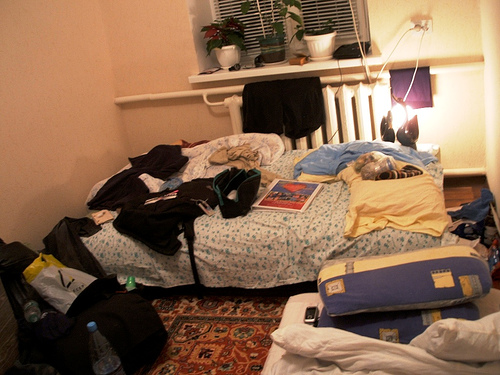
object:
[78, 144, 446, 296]
bed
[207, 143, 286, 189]
thing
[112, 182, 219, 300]
thing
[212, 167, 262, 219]
thing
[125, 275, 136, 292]
bottle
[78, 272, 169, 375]
bag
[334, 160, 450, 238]
pillow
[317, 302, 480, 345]
pillow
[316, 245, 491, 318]
pillow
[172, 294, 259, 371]
rug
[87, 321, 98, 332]
cap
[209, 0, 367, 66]
window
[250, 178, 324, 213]
book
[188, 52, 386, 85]
window sill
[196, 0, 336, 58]
plants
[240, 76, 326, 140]
black shorts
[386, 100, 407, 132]
light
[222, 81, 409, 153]
headboard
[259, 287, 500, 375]
chair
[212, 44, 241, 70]
pot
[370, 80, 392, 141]
lamp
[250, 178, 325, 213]
magazine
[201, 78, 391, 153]
radiator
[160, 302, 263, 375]
floor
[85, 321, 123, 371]
bottle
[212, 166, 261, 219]
bag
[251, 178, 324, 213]
cover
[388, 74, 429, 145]
no shade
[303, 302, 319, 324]
cell phone